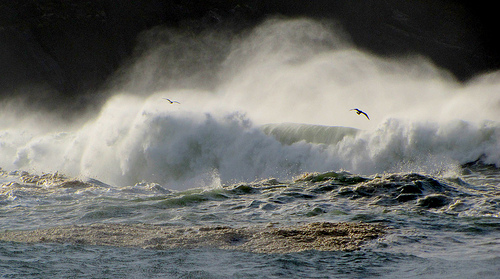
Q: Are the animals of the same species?
A: No, there are both seagulls and birds.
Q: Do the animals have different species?
A: Yes, they are sea gulls and birds.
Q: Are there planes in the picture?
A: No, there are no planes.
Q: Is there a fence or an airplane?
A: No, there are no airplanes or fences.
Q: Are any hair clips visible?
A: No, there are no hair clips.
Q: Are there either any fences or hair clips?
A: No, there are no hair clips or fences.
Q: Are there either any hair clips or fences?
A: No, there are no hair clips or fences.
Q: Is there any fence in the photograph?
A: No, there are no fences.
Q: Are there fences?
A: No, there are no fences.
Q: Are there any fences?
A: No, there are no fences.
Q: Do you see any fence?
A: No, there are no fences.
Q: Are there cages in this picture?
A: No, there are no cages.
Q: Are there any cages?
A: No, there are no cages.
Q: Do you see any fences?
A: No, there are no fences.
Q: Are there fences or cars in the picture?
A: No, there are no fences or cars.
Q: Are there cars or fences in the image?
A: No, there are no fences or cars.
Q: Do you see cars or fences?
A: No, there are no fences or cars.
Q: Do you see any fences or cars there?
A: No, there are no fences or cars.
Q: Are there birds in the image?
A: Yes, there is a bird.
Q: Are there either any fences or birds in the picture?
A: Yes, there is a bird.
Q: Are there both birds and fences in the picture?
A: No, there is a bird but no fences.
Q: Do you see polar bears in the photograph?
A: No, there are no polar bears.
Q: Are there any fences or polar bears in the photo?
A: No, there are no polar bears or fences.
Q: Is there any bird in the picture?
A: Yes, there is a bird.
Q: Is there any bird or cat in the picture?
A: Yes, there is a bird.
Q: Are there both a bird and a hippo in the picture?
A: No, there is a bird but no hippos.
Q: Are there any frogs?
A: No, there are no frogs.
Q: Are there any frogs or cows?
A: No, there are no frogs or cows.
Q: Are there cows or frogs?
A: No, there are no frogs or cows.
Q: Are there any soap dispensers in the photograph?
A: No, there are no soap dispensers.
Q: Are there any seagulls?
A: Yes, there is a seagull.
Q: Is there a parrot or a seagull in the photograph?
A: Yes, there is a seagull.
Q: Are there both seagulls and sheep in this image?
A: No, there is a seagull but no sheep.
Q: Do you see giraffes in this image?
A: No, there are no giraffes.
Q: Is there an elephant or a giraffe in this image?
A: No, there are no giraffes or elephants.